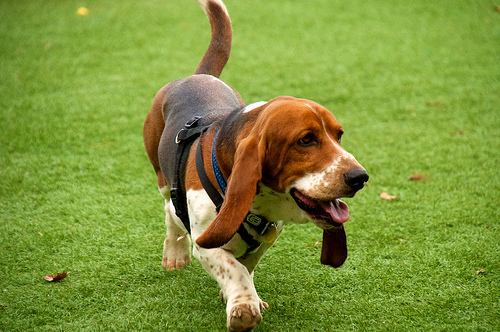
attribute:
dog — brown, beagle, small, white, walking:
[140, 0, 368, 332]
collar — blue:
[208, 118, 282, 237]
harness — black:
[167, 104, 261, 263]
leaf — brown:
[43, 266, 67, 286]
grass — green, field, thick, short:
[0, 0, 498, 332]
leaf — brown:
[378, 187, 397, 204]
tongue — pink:
[318, 197, 350, 226]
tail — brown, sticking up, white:
[191, 0, 233, 80]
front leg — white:
[189, 192, 269, 330]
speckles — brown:
[191, 220, 255, 304]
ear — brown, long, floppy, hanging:
[195, 135, 262, 249]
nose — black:
[343, 163, 369, 193]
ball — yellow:
[74, 5, 90, 20]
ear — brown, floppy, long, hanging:
[314, 218, 349, 268]